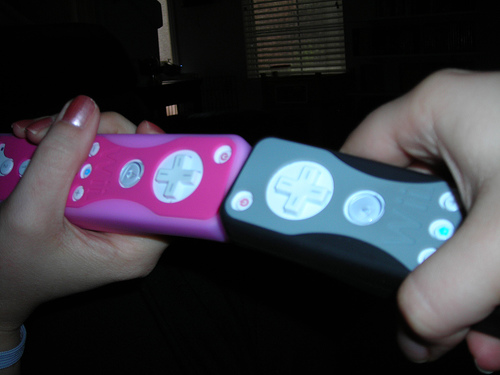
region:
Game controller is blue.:
[228, 127, 471, 279]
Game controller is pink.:
[1, 120, 242, 245]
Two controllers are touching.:
[0, 105, 496, 310]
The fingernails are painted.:
[5, 91, 170, 151]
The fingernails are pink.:
[3, 90, 161, 150]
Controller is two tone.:
[225, 130, 496, 300]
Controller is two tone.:
[1, 116, 242, 251]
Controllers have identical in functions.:
[2, 122, 497, 307]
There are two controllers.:
[0, 123, 499, 309]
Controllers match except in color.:
[0, 117, 499, 302]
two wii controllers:
[51, 111, 378, 278]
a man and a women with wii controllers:
[11, 25, 484, 274]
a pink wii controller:
[97, 130, 214, 225]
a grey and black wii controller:
[269, 132, 427, 272]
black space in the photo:
[163, 263, 287, 350]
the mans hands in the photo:
[383, 107, 495, 272]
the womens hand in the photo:
[16, 85, 173, 286]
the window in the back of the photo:
[184, 3, 408, 78]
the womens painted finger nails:
[39, 103, 141, 148]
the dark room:
[58, 12, 322, 84]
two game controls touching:
[117, 132, 350, 249]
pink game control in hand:
[59, 123, 242, 238]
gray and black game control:
[229, 129, 494, 288]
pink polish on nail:
[55, 90, 99, 140]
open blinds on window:
[235, 23, 358, 87]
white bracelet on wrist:
[4, 315, 34, 370]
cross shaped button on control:
[147, 151, 202, 203]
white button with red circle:
[232, 188, 256, 215]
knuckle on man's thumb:
[384, 271, 451, 344]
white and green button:
[424, 218, 462, 243]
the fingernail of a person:
[61, 92, 102, 129]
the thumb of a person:
[4, 82, 109, 231]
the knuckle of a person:
[391, 275, 461, 345]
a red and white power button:
[233, 192, 253, 214]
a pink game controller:
[0, 114, 265, 240]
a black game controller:
[207, 127, 498, 346]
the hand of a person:
[0, 94, 205, 314]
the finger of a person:
[341, 73, 431, 165]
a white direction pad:
[268, 160, 333, 220]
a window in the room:
[243, 1, 353, 78]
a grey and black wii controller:
[250, 142, 436, 278]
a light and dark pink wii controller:
[87, 114, 236, 237]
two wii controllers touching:
[79, 116, 419, 288]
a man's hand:
[384, 70, 498, 312]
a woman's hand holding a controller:
[7, 93, 176, 280]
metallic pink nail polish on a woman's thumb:
[54, 93, 106, 144]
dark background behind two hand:
[181, 263, 326, 353]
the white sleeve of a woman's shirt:
[5, 327, 18, 371]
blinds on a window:
[254, 5, 351, 76]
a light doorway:
[144, 4, 186, 121]